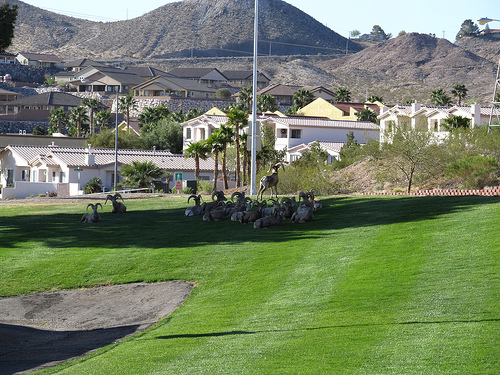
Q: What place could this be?
A: It is a field.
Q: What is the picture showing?
A: It is showing a field.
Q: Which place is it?
A: It is a field.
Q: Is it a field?
A: Yes, it is a field.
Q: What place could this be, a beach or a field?
A: It is a field.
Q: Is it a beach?
A: No, it is a field.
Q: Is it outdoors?
A: Yes, it is outdoors.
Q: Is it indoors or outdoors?
A: It is outdoors.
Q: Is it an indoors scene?
A: No, it is outdoors.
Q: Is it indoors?
A: No, it is outdoors.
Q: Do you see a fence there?
A: No, there are no fences.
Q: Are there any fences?
A: No, there are no fences.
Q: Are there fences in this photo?
A: No, there are no fences.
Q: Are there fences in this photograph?
A: No, there are no fences.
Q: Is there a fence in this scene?
A: No, there are no fences.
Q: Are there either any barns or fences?
A: No, there are no fences or barns.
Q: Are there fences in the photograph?
A: No, there are no fences.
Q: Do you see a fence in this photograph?
A: No, there are no fences.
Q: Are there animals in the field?
A: Yes, there is an animal in the field.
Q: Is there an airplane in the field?
A: No, there is an animal in the field.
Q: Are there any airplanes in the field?
A: No, there is an animal in the field.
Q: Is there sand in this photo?
A: Yes, there is sand.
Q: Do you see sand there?
A: Yes, there is sand.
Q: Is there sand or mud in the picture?
A: Yes, there is sand.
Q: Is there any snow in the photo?
A: No, there is no snow.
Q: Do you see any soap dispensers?
A: No, there are no soap dispensers.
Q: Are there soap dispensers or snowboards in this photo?
A: No, there are no soap dispensers or snowboards.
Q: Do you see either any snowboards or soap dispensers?
A: No, there are no soap dispensers or snowboards.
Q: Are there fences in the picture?
A: No, there are no fences.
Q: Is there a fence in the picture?
A: No, there are no fences.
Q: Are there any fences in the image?
A: No, there are no fences.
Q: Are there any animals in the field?
A: Yes, there are animals in the field.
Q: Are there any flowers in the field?
A: No, there are animals in the field.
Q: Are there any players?
A: No, there are no players.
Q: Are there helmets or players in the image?
A: No, there are no players or helmets.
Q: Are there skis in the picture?
A: No, there are no skis.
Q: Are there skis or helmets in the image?
A: No, there are no skis or helmets.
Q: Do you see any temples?
A: No, there are no temples.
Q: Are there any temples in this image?
A: No, there are no temples.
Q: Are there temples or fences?
A: No, there are no temples or fences.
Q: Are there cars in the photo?
A: No, there are no cars.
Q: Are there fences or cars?
A: No, there are no cars or fences.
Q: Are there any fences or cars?
A: No, there are no fences or cars.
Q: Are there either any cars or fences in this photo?
A: No, there are no fences or cars.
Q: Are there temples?
A: No, there are no temples.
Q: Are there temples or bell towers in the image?
A: No, there are no temples or bell towers.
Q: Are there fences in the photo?
A: No, there are no fences.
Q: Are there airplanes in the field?
A: No, there is an animal in the field.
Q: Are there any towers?
A: No, there are no towers.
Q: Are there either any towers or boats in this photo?
A: No, there are no towers or boats.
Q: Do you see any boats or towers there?
A: No, there are no towers or boats.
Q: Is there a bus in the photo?
A: No, there are no buses.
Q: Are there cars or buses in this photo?
A: No, there are no buses or cars.